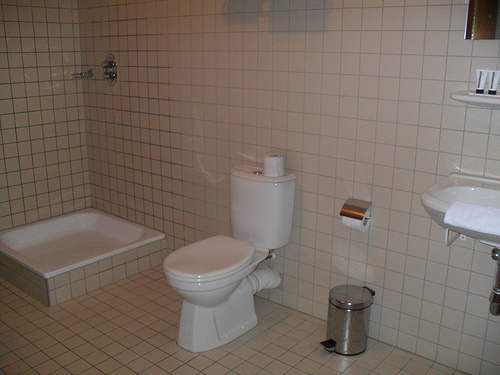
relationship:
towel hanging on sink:
[440, 190, 500, 245] [418, 165, 500, 324]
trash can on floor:
[318, 279, 381, 362] [0, 261, 469, 373]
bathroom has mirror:
[1, 2, 500, 373] [460, 0, 499, 47]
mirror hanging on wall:
[460, 0, 499, 47] [79, 0, 499, 374]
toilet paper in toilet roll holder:
[338, 213, 373, 235] [334, 195, 376, 223]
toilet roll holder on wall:
[334, 195, 376, 223] [79, 0, 499, 374]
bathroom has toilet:
[1, 2, 500, 373] [160, 160, 305, 358]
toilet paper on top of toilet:
[256, 150, 291, 180] [160, 160, 305, 358]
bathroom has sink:
[1, 2, 500, 373] [418, 165, 500, 324]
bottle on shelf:
[472, 66, 491, 98] [449, 88, 500, 114]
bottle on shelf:
[486, 67, 500, 98] [449, 88, 500, 114]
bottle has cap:
[472, 66, 491, 98] [470, 87, 485, 99]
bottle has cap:
[486, 67, 500, 98] [486, 88, 499, 98]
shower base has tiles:
[2, 199, 170, 286] [0, 233, 175, 310]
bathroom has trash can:
[1, 2, 500, 373] [318, 279, 381, 362]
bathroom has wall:
[1, 2, 500, 373] [0, 1, 498, 371]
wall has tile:
[0, 1, 498, 371] [0, 1, 495, 374]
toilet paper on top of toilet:
[338, 213, 373, 235] [160, 160, 305, 358]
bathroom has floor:
[1, 2, 500, 373] [0, 261, 469, 373]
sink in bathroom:
[418, 165, 500, 324] [1, 2, 500, 373]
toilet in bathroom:
[160, 160, 305, 358] [1, 2, 500, 373]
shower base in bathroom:
[2, 199, 170, 286] [1, 2, 500, 373]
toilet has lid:
[160, 160, 305, 358] [160, 227, 258, 282]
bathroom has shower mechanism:
[1, 2, 500, 373] [90, 51, 125, 87]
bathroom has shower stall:
[1, 2, 500, 373] [3, 1, 174, 312]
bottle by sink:
[472, 66, 491, 98] [418, 165, 500, 324]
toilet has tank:
[160, 160, 305, 358] [224, 158, 301, 256]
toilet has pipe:
[160, 160, 305, 358] [246, 265, 288, 297]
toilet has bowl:
[160, 160, 305, 358] [162, 268, 259, 313]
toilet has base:
[160, 160, 305, 358] [172, 278, 271, 354]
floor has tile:
[0, 261, 469, 373] [2, 265, 463, 374]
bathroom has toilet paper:
[1, 2, 500, 373] [256, 150, 291, 180]